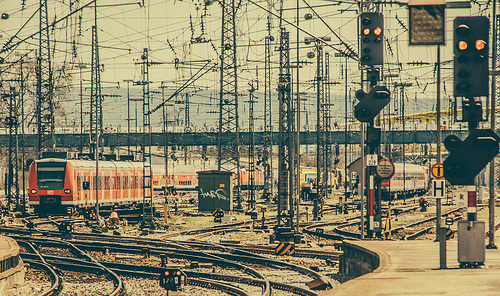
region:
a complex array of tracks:
[19, 218, 347, 293]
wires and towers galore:
[0, 0, 360, 130]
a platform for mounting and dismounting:
[279, 194, 498, 294]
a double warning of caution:
[447, 15, 496, 96]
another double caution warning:
[355, 8, 384, 76]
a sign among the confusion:
[374, 158, 398, 178]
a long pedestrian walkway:
[0, 122, 499, 160]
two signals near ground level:
[54, 217, 186, 293]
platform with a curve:
[284, 203, 498, 291]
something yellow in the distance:
[341, 85, 497, 148]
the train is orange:
[27, 166, 189, 218]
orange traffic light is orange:
[358, 27, 385, 43]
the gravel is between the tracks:
[133, 276, 160, 291]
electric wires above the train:
[128, 25, 201, 44]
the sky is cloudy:
[124, 25, 280, 56]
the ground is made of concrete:
[391, 243, 437, 290]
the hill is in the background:
[113, 85, 240, 120]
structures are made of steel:
[212, 46, 252, 143]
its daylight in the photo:
[3, 8, 496, 293]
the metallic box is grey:
[194, 170, 238, 212]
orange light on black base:
[455, 35, 472, 52]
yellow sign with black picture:
[420, 159, 449, 180]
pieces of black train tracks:
[30, 262, 144, 290]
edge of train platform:
[332, 234, 403, 259]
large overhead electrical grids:
[67, 36, 183, 77]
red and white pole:
[355, 173, 388, 224]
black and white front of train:
[30, 159, 83, 194]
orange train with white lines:
[27, 154, 140, 201]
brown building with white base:
[347, 154, 434, 197]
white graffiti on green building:
[199, 187, 239, 203]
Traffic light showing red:
[354, 8, 395, 77]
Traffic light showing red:
[445, 12, 496, 109]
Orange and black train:
[18, 136, 155, 226]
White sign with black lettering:
[424, 168, 452, 207]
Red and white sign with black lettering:
[372, 151, 402, 185]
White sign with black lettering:
[356, 143, 383, 176]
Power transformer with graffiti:
[182, 153, 244, 228]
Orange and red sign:
[425, 156, 447, 181]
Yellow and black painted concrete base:
[265, 238, 302, 263]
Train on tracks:
[2, 153, 178, 213]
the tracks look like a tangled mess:
[0, 221, 350, 294]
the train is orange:
[29, 157, 264, 207]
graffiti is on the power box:
[198, 183, 230, 200]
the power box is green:
[193, 166, 237, 216]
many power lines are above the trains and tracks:
[1, 1, 498, 141]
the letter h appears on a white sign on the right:
[434, 176, 446, 198]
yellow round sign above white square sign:
[430, 160, 448, 178]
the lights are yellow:
[358, 7, 490, 57]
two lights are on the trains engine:
[28, 185, 71, 198]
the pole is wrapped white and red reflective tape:
[366, 167, 374, 237]